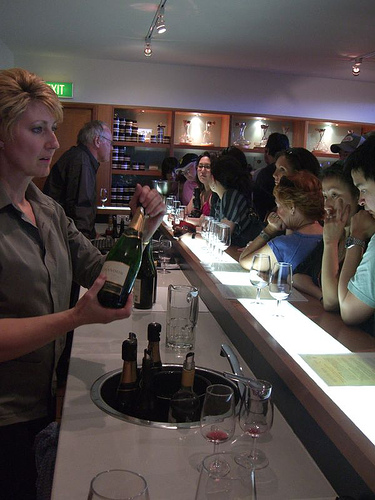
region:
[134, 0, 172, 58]
Track lighting on ceiling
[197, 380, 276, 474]
2 clear wine glasses with a tiny bit of liquid inside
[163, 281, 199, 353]
Clear glass beer mug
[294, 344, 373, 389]
Menu laying on bar top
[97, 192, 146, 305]
Green bottle of champagne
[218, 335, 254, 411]
Silver sink faucet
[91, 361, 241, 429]
Small silver round sink with bottles inside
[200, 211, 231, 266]
Row of wine glasses sitting on bar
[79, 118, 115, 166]
Gray haired man at the bar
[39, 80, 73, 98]
Green exit sign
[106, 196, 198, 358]
Green bottle of champagne.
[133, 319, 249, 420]
Bottles in the counter.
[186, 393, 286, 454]
Glasses with red in bottom.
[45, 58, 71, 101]
Green exit sign on the door.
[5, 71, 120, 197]
Woman with blonde hair.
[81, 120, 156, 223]
Man standing by the bar.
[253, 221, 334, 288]
Light blue shirt on woman.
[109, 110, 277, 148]
Bottles on the shelves.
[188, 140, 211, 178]
Woman with glasses on her face.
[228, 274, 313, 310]
Menu on the bar.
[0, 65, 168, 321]
Woman opening a bottle of champagne.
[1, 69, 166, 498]
Woman behind the bar looking a the patrons.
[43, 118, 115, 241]
Elderly man standing behind the bar.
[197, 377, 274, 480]
Two empty wine glasses on the counter.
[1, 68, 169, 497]
Bartender preparing alcoholic beverages.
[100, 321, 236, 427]
Bottles of alcoholic beverages in the sink.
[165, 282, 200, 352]
Glass mug on the counter.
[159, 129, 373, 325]
Patrons sitting and standing behind the bar.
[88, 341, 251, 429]
Stainless steel sink with a faucet.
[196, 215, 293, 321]
Wine glasses on the counter in front of patrons.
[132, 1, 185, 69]
lighting hanging from ceiling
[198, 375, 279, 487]
empty wine glasses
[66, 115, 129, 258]
man taking orders from behind bar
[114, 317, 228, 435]
multiple bottles of wine chilling on ice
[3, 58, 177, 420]
woman pouring wine from behind bar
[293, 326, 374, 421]
menu laying on bar top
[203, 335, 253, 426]
silver water faucet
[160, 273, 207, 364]
empty glasses water pitcher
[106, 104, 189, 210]
wooden display shelves with product for sale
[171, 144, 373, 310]
patrons waiting for drinks at bar top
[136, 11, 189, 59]
A spotlight on the ceiling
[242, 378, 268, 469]
A wine glass with a little leftover wine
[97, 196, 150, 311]
A bottle of wine to be opened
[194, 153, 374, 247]
A group of people at the bar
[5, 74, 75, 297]
A lady bartender is working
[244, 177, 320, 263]
A middle age woman in blue top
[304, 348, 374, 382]
A liquor list for the guests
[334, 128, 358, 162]
A man in a baseball cap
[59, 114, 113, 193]
A male bartender is answering questions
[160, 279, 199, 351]
An empty water glass